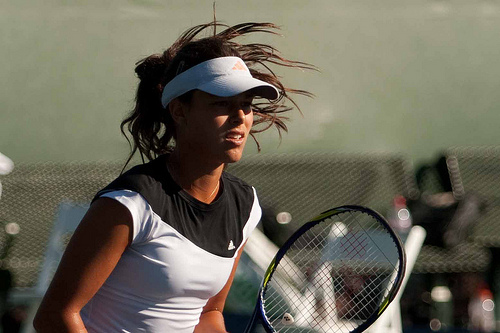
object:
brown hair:
[117, 17, 318, 177]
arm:
[32, 190, 137, 331]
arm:
[190, 239, 251, 332]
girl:
[32, 21, 319, 332]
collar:
[168, 174, 237, 226]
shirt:
[79, 154, 262, 330]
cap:
[155, 55, 278, 107]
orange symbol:
[232, 60, 247, 69]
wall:
[6, 9, 498, 282]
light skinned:
[197, 109, 219, 131]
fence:
[3, 149, 500, 333]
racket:
[245, 205, 410, 333]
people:
[410, 144, 496, 332]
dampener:
[277, 281, 327, 321]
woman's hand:
[198, 308, 235, 333]